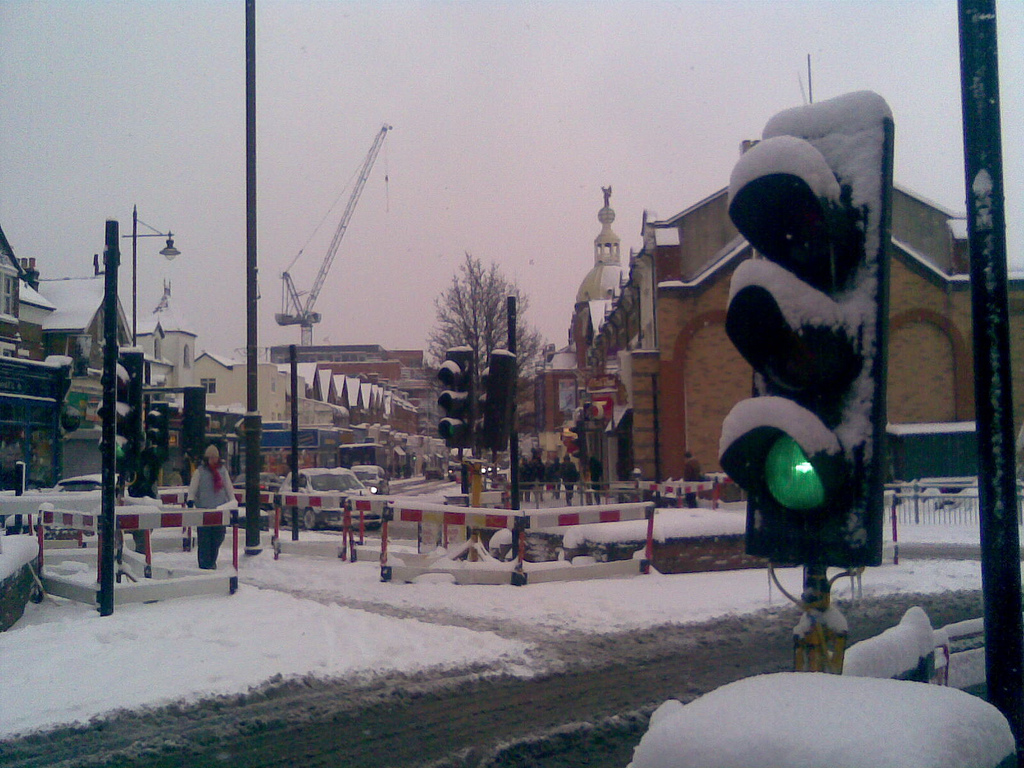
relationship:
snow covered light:
[780, 113, 858, 157] [695, 91, 905, 567]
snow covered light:
[754, 119, 854, 193] [695, 91, 905, 567]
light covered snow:
[695, 91, 905, 567] [756, 122, 847, 170]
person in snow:
[180, 440, 248, 574] [92, 572, 311, 655]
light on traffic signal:
[695, 91, 905, 567] [695, 96, 908, 596]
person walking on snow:
[180, 440, 248, 574] [717, 380, 838, 460]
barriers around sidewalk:
[1, 482, 650, 606] [1, 492, 980, 737]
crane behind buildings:
[266, 108, 413, 355] [1, 164, 1002, 482]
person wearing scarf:
[180, 439, 248, 573] [199, 459, 234, 494]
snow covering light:
[724, 89, 895, 215] [695, 91, 905, 567]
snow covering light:
[720, 256, 872, 343] [695, 91, 905, 567]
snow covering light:
[720, 396, 837, 468] [695, 91, 905, 567]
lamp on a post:
[134, 219, 184, 265] [124, 208, 144, 355]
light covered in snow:
[715, 89, 890, 558] [706, 88, 892, 464]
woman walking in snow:
[181, 441, 248, 573] [717, 380, 838, 460]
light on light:
[715, 89, 890, 558] [695, 91, 905, 567]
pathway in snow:
[203, 572, 586, 657] [1, 480, 982, 766]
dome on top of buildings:
[581, 266, 633, 303] [2, 164, 1002, 482]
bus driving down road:
[336, 438, 397, 490] [317, 469, 471, 536]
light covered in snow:
[695, 91, 903, 567] [706, 88, 892, 464]